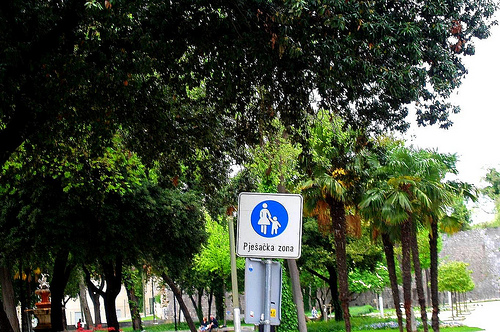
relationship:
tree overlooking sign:
[0, 0, 499, 167] [235, 190, 302, 259]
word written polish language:
[242, 241, 274, 254] [239, 242, 296, 256]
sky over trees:
[409, 1, 499, 177] [2, 15, 492, 329]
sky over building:
[409, 1, 499, 177] [144, 275, 243, 322]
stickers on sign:
[264, 300, 276, 322] [237, 253, 292, 331]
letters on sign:
[241, 240, 251, 253] [234, 190, 306, 259]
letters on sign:
[269, 243, 276, 250] [234, 190, 306, 259]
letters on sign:
[246, 242, 251, 254] [234, 190, 306, 259]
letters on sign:
[273, 242, 283, 252] [234, 190, 306, 259]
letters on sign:
[288, 244, 296, 252] [234, 190, 306, 259]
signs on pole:
[229, 190, 301, 328] [222, 210, 243, 330]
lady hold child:
[256, 202, 271, 234] [268, 212, 280, 232]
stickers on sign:
[239, 261, 283, 321] [220, 174, 305, 260]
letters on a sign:
[239, 237, 293, 257] [235, 190, 302, 259]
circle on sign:
[249, 189, 288, 255] [242, 190, 302, 256]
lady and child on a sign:
[256, 202, 271, 234] [235, 190, 302, 259]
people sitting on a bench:
[200, 314, 217, 330] [143, 297, 219, 332]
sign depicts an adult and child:
[211, 162, 336, 310] [256, 197, 287, 259]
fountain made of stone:
[34, 274, 54, 330] [363, 270, 490, 332]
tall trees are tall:
[322, 163, 433, 332] [322, 163, 433, 332]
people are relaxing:
[175, 308, 238, 330] [183, 309, 224, 332]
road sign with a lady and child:
[388, 297, 500, 331] [268, 215, 282, 235]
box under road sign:
[225, 257, 302, 332] [219, 185, 338, 330]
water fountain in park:
[29, 272, 60, 327] [0, 93, 492, 332]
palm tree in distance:
[420, 159, 472, 329] [26, 52, 470, 285]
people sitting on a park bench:
[200, 314, 217, 330] [196, 324, 256, 330]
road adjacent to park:
[388, 250, 484, 332] [38, 60, 470, 330]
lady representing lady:
[256, 202, 271, 234] [252, 195, 271, 275]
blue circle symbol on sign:
[249, 197, 288, 237] [234, 190, 306, 259]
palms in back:
[292, 122, 452, 329] [278, 114, 486, 332]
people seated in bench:
[196, 313, 221, 330] [197, 319, 232, 328]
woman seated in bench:
[311, 305, 318, 317] [306, 315, 323, 320]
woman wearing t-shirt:
[311, 305, 318, 317] [308, 309, 317, 314]